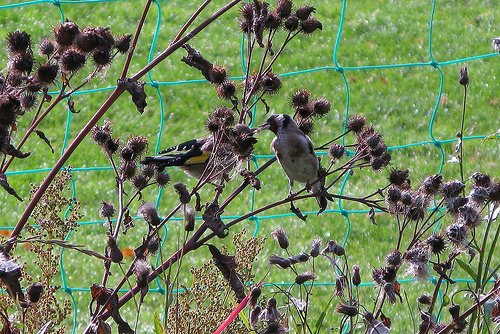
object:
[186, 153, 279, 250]
branch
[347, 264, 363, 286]
flower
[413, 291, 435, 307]
flower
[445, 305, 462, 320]
flower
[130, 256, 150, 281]
flower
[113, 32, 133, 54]
plant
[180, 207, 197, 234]
plant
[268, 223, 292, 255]
plant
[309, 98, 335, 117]
flower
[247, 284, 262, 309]
plant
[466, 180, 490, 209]
prickly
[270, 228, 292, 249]
ball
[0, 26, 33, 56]
purple flower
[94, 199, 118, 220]
plant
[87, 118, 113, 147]
flower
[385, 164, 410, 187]
flower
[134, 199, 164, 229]
plant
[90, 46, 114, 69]
ball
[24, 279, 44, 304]
purple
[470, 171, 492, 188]
ball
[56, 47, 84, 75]
flower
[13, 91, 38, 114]
plant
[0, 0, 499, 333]
fence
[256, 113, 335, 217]
bird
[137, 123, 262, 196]
bird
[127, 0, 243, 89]
branch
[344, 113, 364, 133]
ball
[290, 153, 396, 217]
branch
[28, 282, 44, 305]
ball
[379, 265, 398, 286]
ball